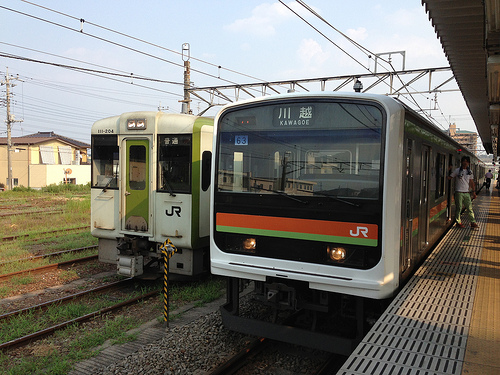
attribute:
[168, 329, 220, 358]
rocks — small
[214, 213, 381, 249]
stripe — orange and green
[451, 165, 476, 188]
t-shirt — white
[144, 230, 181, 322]
pole — metal, orange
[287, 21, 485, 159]
cloud — white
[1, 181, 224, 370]
grass — green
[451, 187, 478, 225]
pants — green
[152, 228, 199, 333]
pole — black and yellow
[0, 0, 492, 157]
sky — blue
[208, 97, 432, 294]
train — green and white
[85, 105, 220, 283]
train car — green and white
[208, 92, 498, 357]
train — orange and green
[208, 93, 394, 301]
front — shiny